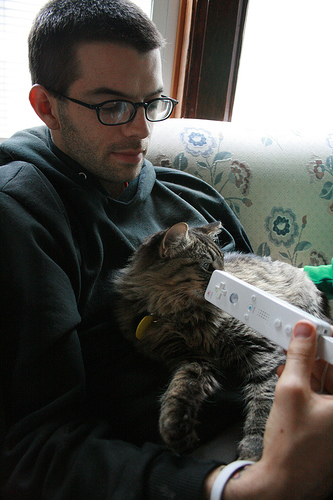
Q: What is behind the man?
A: A window is behind the man.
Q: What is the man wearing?
A: The man is wearing a black sweatshirt.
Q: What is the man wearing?
A: The man is wearing black glasses.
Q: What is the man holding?
A: The man is holding a white game controller.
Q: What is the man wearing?
A: The man is wearing a black hoodie.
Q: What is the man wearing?
A: A white bracelet.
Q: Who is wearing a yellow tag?
A: A brown and black cat.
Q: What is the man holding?
A: A black and brown cat.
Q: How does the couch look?
A: The couch has a floral design.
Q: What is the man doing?
A: The man is seated with the cat.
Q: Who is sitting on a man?
A: A cat.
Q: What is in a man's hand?
A: A Wii remote.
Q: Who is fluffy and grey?
A: A cat.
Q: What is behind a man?
A: A floral couch.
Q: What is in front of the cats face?
A: A wii.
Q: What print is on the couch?
A: Flowers.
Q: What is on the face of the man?
A: Glasses.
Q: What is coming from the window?
A: Light.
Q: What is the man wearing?
A: A hoodie.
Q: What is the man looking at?
A: The cat.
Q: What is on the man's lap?
A: A cat.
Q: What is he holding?
A: A remote.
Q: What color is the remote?
A: White.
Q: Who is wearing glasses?
A: The man.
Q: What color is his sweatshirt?
A: Black.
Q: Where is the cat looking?
A: Away from the man.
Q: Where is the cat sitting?
A: On the man's lap.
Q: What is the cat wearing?
A: A collar.